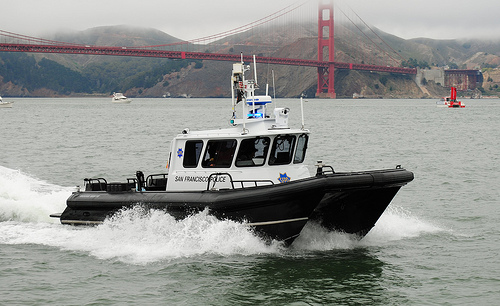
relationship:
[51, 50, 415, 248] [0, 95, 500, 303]
boat in water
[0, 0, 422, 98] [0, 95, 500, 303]
bridge in water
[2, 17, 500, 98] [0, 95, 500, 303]
mountain beside water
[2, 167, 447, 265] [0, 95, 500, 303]
wave in water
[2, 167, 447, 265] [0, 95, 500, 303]
wave inside water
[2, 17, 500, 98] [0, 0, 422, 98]
mountain behind bridge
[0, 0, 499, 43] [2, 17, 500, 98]
fog on top of mountain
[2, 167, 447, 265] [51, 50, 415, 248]
wave behind boat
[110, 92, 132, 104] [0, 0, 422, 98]
boat under bridge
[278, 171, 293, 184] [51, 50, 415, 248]
star apart of boat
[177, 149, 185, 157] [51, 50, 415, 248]
star apart of boat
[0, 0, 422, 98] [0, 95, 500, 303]
bridge over water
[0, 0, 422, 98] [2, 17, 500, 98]
bridge beside mountain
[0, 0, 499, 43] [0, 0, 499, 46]
fog in sky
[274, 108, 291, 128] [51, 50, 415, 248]
camera apart of boat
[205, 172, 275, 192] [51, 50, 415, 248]
railing apart of boat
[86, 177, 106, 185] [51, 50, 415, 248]
railing apart of boat